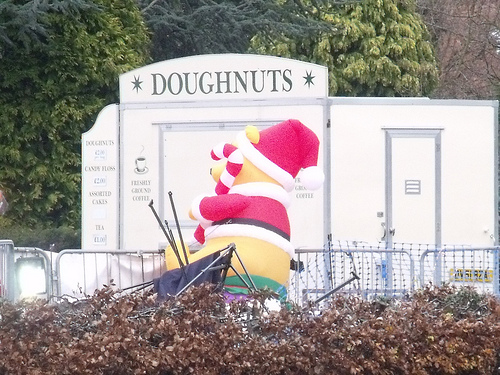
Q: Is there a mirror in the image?
A: Yes, there is a mirror.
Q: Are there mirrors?
A: Yes, there is a mirror.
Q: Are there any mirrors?
A: Yes, there is a mirror.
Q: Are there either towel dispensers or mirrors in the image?
A: Yes, there is a mirror.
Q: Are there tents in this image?
A: No, there are no tents.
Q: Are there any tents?
A: No, there are no tents.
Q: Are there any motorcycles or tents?
A: No, there are no tents or motorcycles.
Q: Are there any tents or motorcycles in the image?
A: No, there are no tents or motorcycles.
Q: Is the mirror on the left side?
A: Yes, the mirror is on the left of the image.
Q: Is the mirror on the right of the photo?
A: No, the mirror is on the left of the image.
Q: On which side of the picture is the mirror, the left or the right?
A: The mirror is on the left of the image.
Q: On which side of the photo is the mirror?
A: The mirror is on the left of the image.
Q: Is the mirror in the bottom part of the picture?
A: Yes, the mirror is in the bottom of the image.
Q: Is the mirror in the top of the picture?
A: No, the mirror is in the bottom of the image.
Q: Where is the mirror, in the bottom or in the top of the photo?
A: The mirror is in the bottom of the image.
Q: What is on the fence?
A: The mirror is on the fence.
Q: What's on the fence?
A: The mirror is on the fence.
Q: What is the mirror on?
A: The mirror is on the fence.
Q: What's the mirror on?
A: The mirror is on the fence.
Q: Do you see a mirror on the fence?
A: Yes, there is a mirror on the fence.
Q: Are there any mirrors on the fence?
A: Yes, there is a mirror on the fence.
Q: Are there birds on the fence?
A: No, there is a mirror on the fence.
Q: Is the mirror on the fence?
A: Yes, the mirror is on the fence.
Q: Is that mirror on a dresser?
A: No, the mirror is on the fence.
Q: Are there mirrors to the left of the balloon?
A: Yes, there is a mirror to the left of the balloon.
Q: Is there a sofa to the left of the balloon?
A: No, there is a mirror to the left of the balloon.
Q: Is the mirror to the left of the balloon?
A: Yes, the mirror is to the left of the balloon.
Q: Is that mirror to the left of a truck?
A: No, the mirror is to the left of the balloon.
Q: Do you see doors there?
A: Yes, there is a door.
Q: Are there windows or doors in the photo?
A: Yes, there is a door.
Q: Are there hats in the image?
A: Yes, there is a hat.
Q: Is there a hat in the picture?
A: Yes, there is a hat.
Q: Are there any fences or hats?
A: Yes, there is a hat.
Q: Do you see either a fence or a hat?
A: Yes, there is a hat.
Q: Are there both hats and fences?
A: Yes, there are both a hat and a fence.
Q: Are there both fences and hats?
A: Yes, there are both a hat and a fence.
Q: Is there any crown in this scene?
A: No, there are no crowns.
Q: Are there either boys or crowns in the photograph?
A: No, there are no crowns or boys.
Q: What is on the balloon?
A: The hat is on the balloon.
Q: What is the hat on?
A: The hat is on the balloon.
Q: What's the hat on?
A: The hat is on the balloon.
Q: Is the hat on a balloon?
A: Yes, the hat is on a balloon.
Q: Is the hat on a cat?
A: No, the hat is on a balloon.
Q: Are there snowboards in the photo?
A: No, there are no snowboards.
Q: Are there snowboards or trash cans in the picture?
A: No, there are no snowboards or trash cans.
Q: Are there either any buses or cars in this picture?
A: No, there are no buses or cars.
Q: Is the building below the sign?
A: Yes, the building is below the sign.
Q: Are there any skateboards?
A: No, there are no skateboards.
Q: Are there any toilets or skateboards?
A: No, there are no skateboards or toilets.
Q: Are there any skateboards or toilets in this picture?
A: No, there are no skateboards or toilets.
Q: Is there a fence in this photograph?
A: Yes, there is a fence.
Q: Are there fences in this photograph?
A: Yes, there is a fence.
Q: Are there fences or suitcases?
A: Yes, there is a fence.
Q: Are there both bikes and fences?
A: No, there is a fence but no bikes.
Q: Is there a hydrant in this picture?
A: No, there are no fire hydrants.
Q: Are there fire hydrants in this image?
A: No, there are no fire hydrants.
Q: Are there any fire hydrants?
A: No, there are no fire hydrants.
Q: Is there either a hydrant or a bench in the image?
A: No, there are no fire hydrants or benches.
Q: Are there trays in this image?
A: No, there are no trays.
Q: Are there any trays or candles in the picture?
A: No, there are no trays or candles.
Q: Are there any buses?
A: No, there are no buses.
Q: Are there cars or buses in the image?
A: No, there are no buses or cars.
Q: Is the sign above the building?
A: Yes, the sign is above the building.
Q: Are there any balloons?
A: Yes, there is a balloon.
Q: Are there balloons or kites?
A: Yes, there is a balloon.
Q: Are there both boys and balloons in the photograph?
A: No, there is a balloon but no boys.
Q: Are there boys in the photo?
A: No, there are no boys.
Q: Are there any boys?
A: No, there are no boys.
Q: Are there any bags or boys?
A: No, there are no boys or bags.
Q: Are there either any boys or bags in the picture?
A: No, there are no boys or bags.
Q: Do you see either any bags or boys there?
A: No, there are no boys or bags.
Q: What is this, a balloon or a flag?
A: This is a balloon.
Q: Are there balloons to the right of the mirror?
A: Yes, there is a balloon to the right of the mirror.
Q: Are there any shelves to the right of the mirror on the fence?
A: No, there is a balloon to the right of the mirror.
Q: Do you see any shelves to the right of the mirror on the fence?
A: No, there is a balloon to the right of the mirror.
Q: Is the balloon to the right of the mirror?
A: Yes, the balloon is to the right of the mirror.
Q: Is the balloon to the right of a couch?
A: No, the balloon is to the right of the mirror.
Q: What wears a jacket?
A: The balloon wears a jacket.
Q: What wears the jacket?
A: The balloon wears a jacket.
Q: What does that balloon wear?
A: The balloon wears a jacket.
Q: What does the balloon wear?
A: The balloon wears a jacket.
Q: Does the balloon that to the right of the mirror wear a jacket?
A: Yes, the balloon wears a jacket.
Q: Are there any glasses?
A: No, there are no glasses.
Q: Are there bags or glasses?
A: No, there are no glasses or bags.